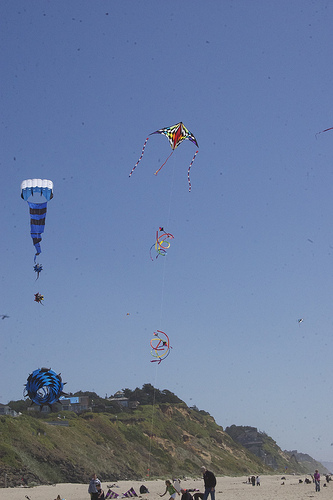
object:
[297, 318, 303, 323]
airplane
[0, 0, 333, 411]
sky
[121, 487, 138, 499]
kite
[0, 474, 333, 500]
sand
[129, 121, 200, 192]
airplane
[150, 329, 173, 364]
kite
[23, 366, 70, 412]
kite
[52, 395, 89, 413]
house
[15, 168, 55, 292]
blue kite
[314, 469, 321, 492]
people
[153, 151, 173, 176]
tail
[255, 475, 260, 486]
people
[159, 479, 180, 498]
girl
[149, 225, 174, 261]
kite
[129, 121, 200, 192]
kite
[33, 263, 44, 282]
kite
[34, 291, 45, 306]
kite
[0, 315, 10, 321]
kite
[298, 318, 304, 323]
kite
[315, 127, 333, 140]
kite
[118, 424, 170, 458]
grassy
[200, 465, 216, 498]
man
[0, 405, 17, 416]
house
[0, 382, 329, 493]
hill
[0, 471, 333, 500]
beach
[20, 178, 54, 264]
airplane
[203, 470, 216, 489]
shirt